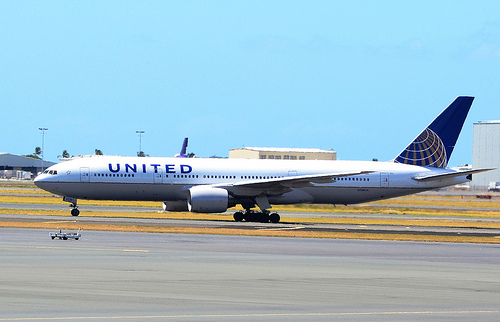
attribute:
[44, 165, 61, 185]
window — small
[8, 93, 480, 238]
plane — blue, white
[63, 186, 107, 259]
wheel — back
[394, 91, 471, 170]
tail — dark blue